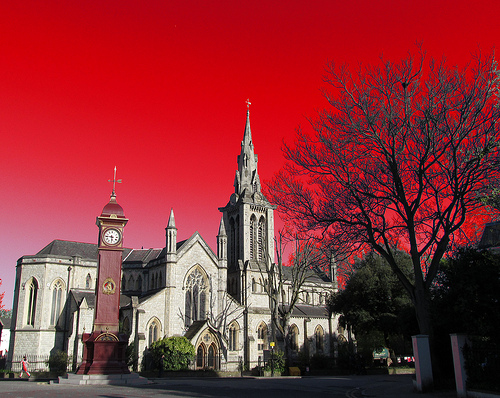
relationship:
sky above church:
[4, 1, 496, 229] [3, 100, 415, 385]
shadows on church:
[283, 327, 362, 376] [17, 102, 384, 380]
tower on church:
[94, 167, 126, 369] [3, 100, 415, 385]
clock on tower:
[102, 228, 119, 246] [81, 167, 138, 378]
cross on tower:
[106, 163, 122, 198] [84, 197, 124, 374]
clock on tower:
[102, 228, 121, 246] [84, 197, 124, 374]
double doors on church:
[194, 343, 217, 370] [17, 102, 384, 380]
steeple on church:
[226, 99, 275, 212] [111, 68, 417, 350]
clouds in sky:
[0, 0, 497, 309] [2, 3, 498, 185]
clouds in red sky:
[0, 0, 497, 309] [0, 3, 500, 291]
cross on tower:
[108, 165, 123, 196] [51, 176, 163, 361]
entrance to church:
[194, 325, 220, 374] [8, 97, 352, 373]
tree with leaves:
[325, 242, 430, 375] [328, 239, 426, 331]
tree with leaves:
[431, 240, 496, 382] [434, 235, 499, 325]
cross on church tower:
[241, 92, 256, 110] [211, 86, 286, 276]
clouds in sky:
[0, 0, 497, 309] [8, 5, 262, 82]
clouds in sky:
[0, 0, 497, 309] [15, 15, 336, 145]